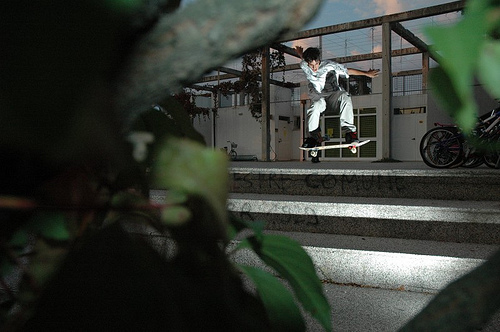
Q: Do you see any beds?
A: No, there are no beds.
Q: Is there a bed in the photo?
A: No, there are no beds.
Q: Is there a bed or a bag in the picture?
A: No, there are no beds or bags.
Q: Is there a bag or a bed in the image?
A: No, there are no beds or bags.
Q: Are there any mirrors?
A: No, there are no mirrors.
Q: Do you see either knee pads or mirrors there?
A: No, there are no mirrors or knee pads.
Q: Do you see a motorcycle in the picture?
A: Yes, there is a motorcycle.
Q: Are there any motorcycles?
A: Yes, there is a motorcycle.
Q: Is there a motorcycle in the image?
A: Yes, there is a motorcycle.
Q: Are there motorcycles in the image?
A: Yes, there is a motorcycle.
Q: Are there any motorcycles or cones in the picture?
A: Yes, there is a motorcycle.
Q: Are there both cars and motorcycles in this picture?
A: No, there is a motorcycle but no cars.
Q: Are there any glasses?
A: No, there are no glasses.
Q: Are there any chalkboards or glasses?
A: No, there are no glasses or chalkboards.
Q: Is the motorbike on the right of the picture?
A: Yes, the motorbike is on the right of the image.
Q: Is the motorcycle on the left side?
A: No, the motorcycle is on the right of the image.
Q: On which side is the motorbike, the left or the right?
A: The motorbike is on the right of the image.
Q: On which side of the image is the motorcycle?
A: The motorcycle is on the right of the image.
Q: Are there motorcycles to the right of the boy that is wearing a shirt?
A: Yes, there is a motorcycle to the right of the boy.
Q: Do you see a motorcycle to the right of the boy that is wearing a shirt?
A: Yes, there is a motorcycle to the right of the boy.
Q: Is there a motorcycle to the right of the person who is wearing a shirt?
A: Yes, there is a motorcycle to the right of the boy.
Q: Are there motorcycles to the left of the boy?
A: No, the motorcycle is to the right of the boy.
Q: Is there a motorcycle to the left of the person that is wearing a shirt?
A: No, the motorcycle is to the right of the boy.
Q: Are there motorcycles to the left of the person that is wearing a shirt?
A: No, the motorcycle is to the right of the boy.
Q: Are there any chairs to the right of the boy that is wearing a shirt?
A: No, there is a motorcycle to the right of the boy.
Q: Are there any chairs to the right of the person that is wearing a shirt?
A: No, there is a motorcycle to the right of the boy.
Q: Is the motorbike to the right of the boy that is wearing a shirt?
A: Yes, the motorbike is to the right of the boy.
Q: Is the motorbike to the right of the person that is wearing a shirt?
A: Yes, the motorbike is to the right of the boy.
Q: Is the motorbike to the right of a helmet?
A: No, the motorbike is to the right of the boy.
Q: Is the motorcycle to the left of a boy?
A: No, the motorcycle is to the right of a boy.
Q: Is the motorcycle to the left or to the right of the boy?
A: The motorcycle is to the right of the boy.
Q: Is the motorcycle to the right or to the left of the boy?
A: The motorcycle is to the right of the boy.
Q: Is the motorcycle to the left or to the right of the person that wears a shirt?
A: The motorcycle is to the right of the boy.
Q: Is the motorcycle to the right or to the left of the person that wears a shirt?
A: The motorcycle is to the right of the boy.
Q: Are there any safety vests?
A: No, there are no safety vests.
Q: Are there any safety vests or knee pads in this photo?
A: No, there are no safety vests or knee pads.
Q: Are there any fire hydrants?
A: No, there are no fire hydrants.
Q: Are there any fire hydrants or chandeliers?
A: No, there are no fire hydrants or chandeliers.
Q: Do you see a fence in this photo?
A: No, there are no fences.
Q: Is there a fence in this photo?
A: No, there are no fences.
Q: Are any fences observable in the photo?
A: No, there are no fences.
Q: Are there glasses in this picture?
A: No, there are no glasses.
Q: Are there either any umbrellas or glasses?
A: No, there are no glasses or umbrellas.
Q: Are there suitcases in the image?
A: No, there are no suitcases.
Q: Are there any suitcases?
A: No, there are no suitcases.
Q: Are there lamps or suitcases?
A: No, there are no suitcases or lamps.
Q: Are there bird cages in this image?
A: No, there are no bird cages.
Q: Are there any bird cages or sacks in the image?
A: No, there are no bird cages or sacks.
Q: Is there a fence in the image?
A: No, there are no fences.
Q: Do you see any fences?
A: No, there are no fences.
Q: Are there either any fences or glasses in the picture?
A: No, there are no fences or glasses.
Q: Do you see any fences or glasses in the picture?
A: No, there are no fences or glasses.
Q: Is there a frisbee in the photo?
A: No, there are no frisbees.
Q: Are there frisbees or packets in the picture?
A: No, there are no frisbees or packets.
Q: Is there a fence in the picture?
A: No, there are no fences.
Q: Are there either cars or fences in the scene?
A: No, there are no fences or cars.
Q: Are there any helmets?
A: No, there are no helmets.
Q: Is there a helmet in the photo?
A: No, there are no helmets.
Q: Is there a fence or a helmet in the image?
A: No, there are no helmets or fences.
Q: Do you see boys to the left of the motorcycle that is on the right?
A: Yes, there is a boy to the left of the motorbike.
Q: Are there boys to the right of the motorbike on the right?
A: No, the boy is to the left of the motorcycle.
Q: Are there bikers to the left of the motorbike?
A: No, there is a boy to the left of the motorbike.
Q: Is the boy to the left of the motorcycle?
A: Yes, the boy is to the left of the motorcycle.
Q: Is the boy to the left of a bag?
A: No, the boy is to the left of the motorcycle.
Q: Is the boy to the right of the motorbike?
A: No, the boy is to the left of the motorbike.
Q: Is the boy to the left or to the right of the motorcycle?
A: The boy is to the left of the motorcycle.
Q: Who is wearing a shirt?
A: The boy is wearing a shirt.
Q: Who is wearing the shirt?
A: The boy is wearing a shirt.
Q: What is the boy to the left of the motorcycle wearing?
A: The boy is wearing a shirt.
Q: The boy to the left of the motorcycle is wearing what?
A: The boy is wearing a shirt.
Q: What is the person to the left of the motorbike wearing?
A: The boy is wearing a shirt.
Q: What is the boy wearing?
A: The boy is wearing a shirt.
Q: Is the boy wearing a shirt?
A: Yes, the boy is wearing a shirt.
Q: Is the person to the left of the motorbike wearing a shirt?
A: Yes, the boy is wearing a shirt.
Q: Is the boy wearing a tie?
A: No, the boy is wearing a shirt.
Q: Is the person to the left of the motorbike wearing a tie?
A: No, the boy is wearing a shirt.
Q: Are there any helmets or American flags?
A: No, there are no helmets or American flags.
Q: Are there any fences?
A: No, there are no fences.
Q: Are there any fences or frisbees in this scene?
A: No, there are no fences or frisbees.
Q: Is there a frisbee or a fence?
A: No, there are no fences or frisbees.